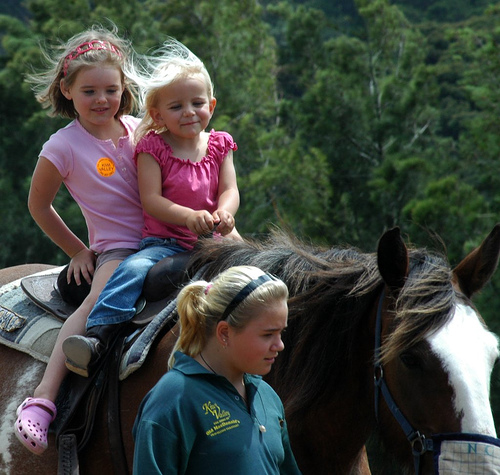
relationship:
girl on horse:
[131, 41, 246, 297] [3, 227, 498, 474]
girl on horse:
[10, 27, 151, 456] [3, 227, 498, 474]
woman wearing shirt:
[123, 264, 306, 474] [125, 352, 303, 470]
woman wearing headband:
[123, 264, 306, 474] [220, 264, 279, 319]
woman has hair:
[123, 264, 306, 474] [164, 264, 292, 366]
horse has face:
[3, 227, 498, 474] [420, 302, 499, 474]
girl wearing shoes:
[131, 41, 246, 297] [59, 327, 112, 379]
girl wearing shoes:
[10, 27, 151, 456] [12, 391, 64, 463]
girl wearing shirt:
[131, 41, 246, 297] [135, 129, 248, 248]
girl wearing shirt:
[10, 27, 151, 456] [41, 114, 154, 249]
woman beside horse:
[123, 264, 306, 474] [3, 227, 498, 474]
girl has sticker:
[10, 27, 151, 456] [95, 154, 118, 178]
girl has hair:
[131, 41, 246, 297] [127, 34, 217, 147]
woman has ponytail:
[123, 264, 306, 474] [166, 275, 216, 369]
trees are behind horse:
[2, 2, 499, 327] [3, 227, 498, 474]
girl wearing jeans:
[131, 41, 246, 297] [84, 235, 183, 346]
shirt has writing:
[125, 352, 303, 470] [201, 400, 241, 437]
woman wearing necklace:
[123, 264, 306, 474] [195, 347, 271, 434]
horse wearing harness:
[3, 227, 498, 474] [368, 281, 499, 472]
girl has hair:
[10, 27, 151, 456] [20, 17, 135, 121]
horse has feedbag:
[3, 227, 498, 474] [416, 428, 493, 474]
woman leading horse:
[123, 264, 306, 474] [3, 227, 498, 474]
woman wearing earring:
[123, 264, 306, 474] [220, 337, 236, 349]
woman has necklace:
[123, 264, 306, 474] [195, 347, 271, 434]